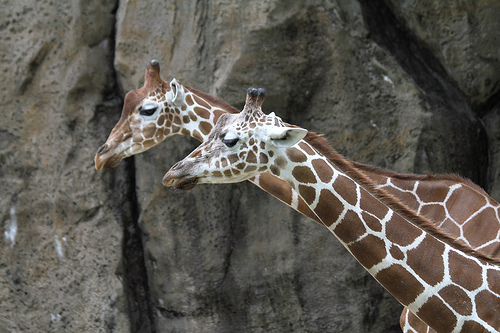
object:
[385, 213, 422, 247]
spot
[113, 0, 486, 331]
rock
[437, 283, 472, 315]
spot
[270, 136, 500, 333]
neck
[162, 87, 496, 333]
giraffe